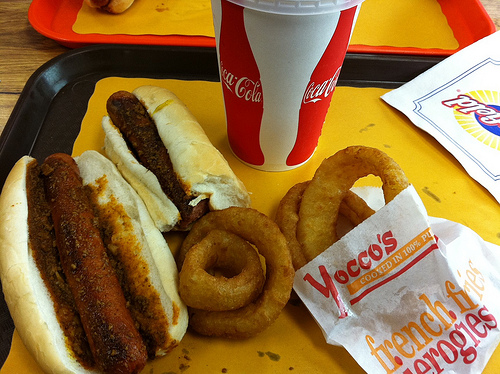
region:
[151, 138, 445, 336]
onion rings on a tray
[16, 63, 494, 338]
a black tray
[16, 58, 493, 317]
a black tray with food on it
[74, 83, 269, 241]
a hotdog in a bun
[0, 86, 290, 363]
two hotdogs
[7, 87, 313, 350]
two hotdogs in buns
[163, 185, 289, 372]
two onion rings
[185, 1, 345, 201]
a white and red cup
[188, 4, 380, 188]
a coca-cola cup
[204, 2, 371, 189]
a red and white coke up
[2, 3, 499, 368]
lunch on a tray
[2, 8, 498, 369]
dinner on a tray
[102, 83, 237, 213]
hot dog on a tray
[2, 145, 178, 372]
a chili dog on a tray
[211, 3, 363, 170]
a red and white paper cup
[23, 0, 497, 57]
an orange tray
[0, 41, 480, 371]
a brown tray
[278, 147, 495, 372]
onion rings in paper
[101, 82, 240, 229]
a half eaten chili dog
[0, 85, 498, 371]
Two chili dogs with onion rings.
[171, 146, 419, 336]
The onion rings are breaded and fried.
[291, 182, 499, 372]
Some onion rings in a paper holder.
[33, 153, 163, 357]
Chili on the hotdog and the bun.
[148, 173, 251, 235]
A bite taken out of the chili dog.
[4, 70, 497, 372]
Yellow paper under the food.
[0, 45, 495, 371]
A black food tray.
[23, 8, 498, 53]
A red food tray lined with yellow paper.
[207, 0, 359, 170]
Soft drink in a paper cup.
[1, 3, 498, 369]
Trays on top of a wooden table.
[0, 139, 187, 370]
grilled hotdog inside bun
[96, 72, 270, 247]
partially eaten hotdog with chili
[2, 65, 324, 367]
fried onion rings next to hotdog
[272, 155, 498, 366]
fried onion rings in bag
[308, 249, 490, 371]
red, orange, and white bag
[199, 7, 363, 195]
red and white paper cup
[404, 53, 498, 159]
red outline around white letters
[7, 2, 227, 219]
orange and black plastic serving trays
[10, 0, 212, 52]
orange plastic tray with yellow paper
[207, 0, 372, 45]
plastic lid on paper cup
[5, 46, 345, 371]
hotdogs on a tray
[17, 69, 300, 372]
cooked hotdogs on a tray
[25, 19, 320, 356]
two hotdogs on a tray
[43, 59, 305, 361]
two cooked hotdogs on a tray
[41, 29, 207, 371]
hotdogs on a black tray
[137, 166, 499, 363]
fried onion rings on a tray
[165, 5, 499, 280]
a drink on a tray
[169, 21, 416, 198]
a drink on a black tray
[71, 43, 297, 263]
a hotdog with bite taken out